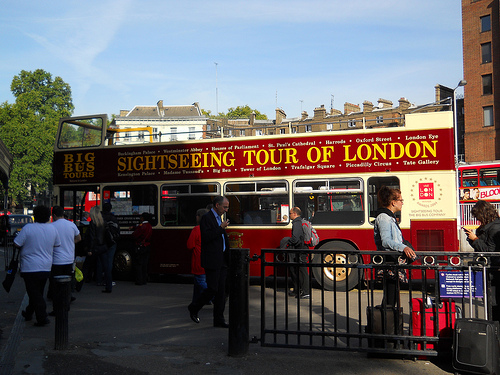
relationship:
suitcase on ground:
[446, 256, 498, 373] [1, 245, 498, 374]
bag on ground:
[413, 297, 455, 359] [2, 275, 484, 370]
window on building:
[478, 40, 495, 77] [456, 2, 491, 159]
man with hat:
[48, 205, 88, 322] [70, 262, 85, 291]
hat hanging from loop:
[70, 262, 85, 291] [56, 265, 78, 270]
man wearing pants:
[279, 206, 319, 300] [292, 242, 312, 292]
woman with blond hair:
[82, 204, 125, 291] [86, 207, 107, 232]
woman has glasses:
[373, 185, 416, 308] [398, 199, 405, 200]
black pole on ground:
[230, 240, 257, 361] [54, 271, 464, 373]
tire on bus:
[310, 239, 365, 291] [48, 113, 460, 291]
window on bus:
[59, 172, 372, 231] [48, 113, 460, 291]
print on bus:
[62, 147, 97, 177] [50, 102, 460, 279]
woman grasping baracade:
[372, 183, 409, 346] [254, 243, 499, 365]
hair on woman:
[377, 182, 402, 207] [372, 183, 409, 346]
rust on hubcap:
[333, 258, 345, 266] [320, 242, 353, 282]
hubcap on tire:
[320, 242, 353, 282] [300, 228, 366, 289]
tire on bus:
[300, 228, 366, 289] [33, 80, 498, 312]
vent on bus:
[411, 215, 448, 266] [47, 113, 460, 291]